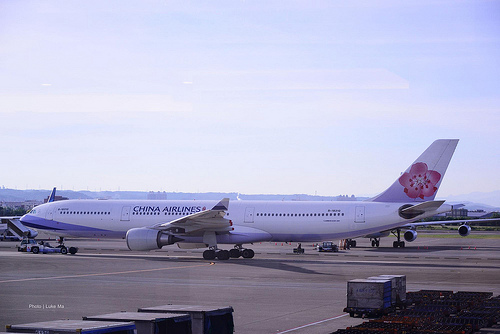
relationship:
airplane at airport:
[19, 136, 460, 265] [5, 1, 500, 332]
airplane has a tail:
[19, 136, 460, 265] [373, 138, 462, 201]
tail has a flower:
[373, 138, 462, 201] [401, 162, 442, 198]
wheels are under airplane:
[201, 247, 256, 261] [19, 136, 460, 265]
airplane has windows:
[19, 136, 460, 265] [55, 210, 113, 215]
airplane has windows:
[19, 136, 460, 265] [131, 211, 194, 216]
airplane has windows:
[19, 136, 460, 265] [255, 212, 346, 218]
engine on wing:
[127, 227, 176, 249] [162, 196, 234, 237]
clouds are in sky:
[5, 92, 190, 114] [1, 1, 499, 193]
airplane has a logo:
[19, 136, 460, 265] [132, 204, 208, 213]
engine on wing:
[458, 224, 472, 238] [411, 218, 499, 227]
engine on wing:
[404, 225, 418, 242] [411, 218, 499, 227]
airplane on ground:
[19, 136, 460, 265] [2, 236, 499, 333]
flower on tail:
[401, 162, 442, 198] [373, 138, 462, 201]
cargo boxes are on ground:
[346, 274, 407, 310] [2, 236, 499, 333]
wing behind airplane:
[411, 218, 499, 227] [19, 136, 460, 265]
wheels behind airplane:
[391, 241, 409, 249] [19, 136, 460, 265]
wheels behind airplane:
[372, 240, 381, 247] [19, 136, 460, 265]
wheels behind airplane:
[348, 238, 359, 250] [19, 136, 460, 265]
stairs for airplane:
[10, 219, 35, 239] [0, 188, 58, 239]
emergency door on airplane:
[354, 204, 367, 226] [19, 136, 460, 265]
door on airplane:
[119, 205, 132, 222] [19, 136, 460, 265]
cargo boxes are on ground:
[9, 304, 235, 334] [2, 236, 499, 333]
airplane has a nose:
[19, 136, 460, 265] [18, 214, 38, 229]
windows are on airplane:
[55, 210, 113, 215] [19, 136, 460, 265]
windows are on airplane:
[131, 211, 194, 216] [19, 136, 460, 265]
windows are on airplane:
[255, 212, 346, 218] [19, 136, 460, 265]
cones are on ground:
[415, 241, 431, 252] [2, 236, 499, 333]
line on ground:
[2, 258, 214, 281] [2, 236, 499, 333]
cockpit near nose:
[28, 204, 51, 217] [18, 214, 38, 229]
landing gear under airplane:
[204, 240, 259, 263] [19, 136, 460, 265]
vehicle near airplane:
[17, 237, 72, 255] [19, 136, 460, 265]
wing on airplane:
[162, 196, 234, 237] [19, 136, 460, 265]